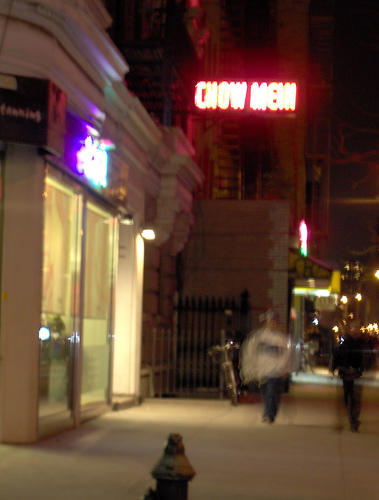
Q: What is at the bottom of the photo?
A: Hydrant.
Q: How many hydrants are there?
A: One.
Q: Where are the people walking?
A: On the sidewalk.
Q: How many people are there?
A: Two.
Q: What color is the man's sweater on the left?
A: White.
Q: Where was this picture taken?
A: At a city.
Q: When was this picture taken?
A: At night time.